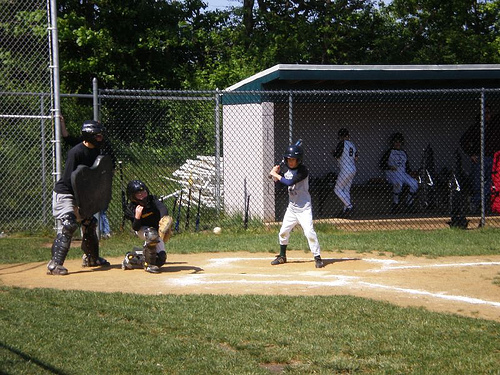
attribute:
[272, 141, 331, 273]
boy — team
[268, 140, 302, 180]
bat — black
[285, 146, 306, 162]
helmet — blue, black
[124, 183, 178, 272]
catcher — bend, crouched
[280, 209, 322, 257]
pants — white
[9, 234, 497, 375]
field — green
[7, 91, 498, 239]
fence — silver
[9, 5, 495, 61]
trees — green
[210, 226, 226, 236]
baseball — white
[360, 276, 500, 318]
lines — white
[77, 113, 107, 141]
helmet — black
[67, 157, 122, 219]
shield — black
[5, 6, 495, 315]
picture — daytime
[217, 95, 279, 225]
shed — white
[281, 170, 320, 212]
shirt — white, blue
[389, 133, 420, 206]
boy — sitting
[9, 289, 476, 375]
grass — green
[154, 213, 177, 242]
glove — tan